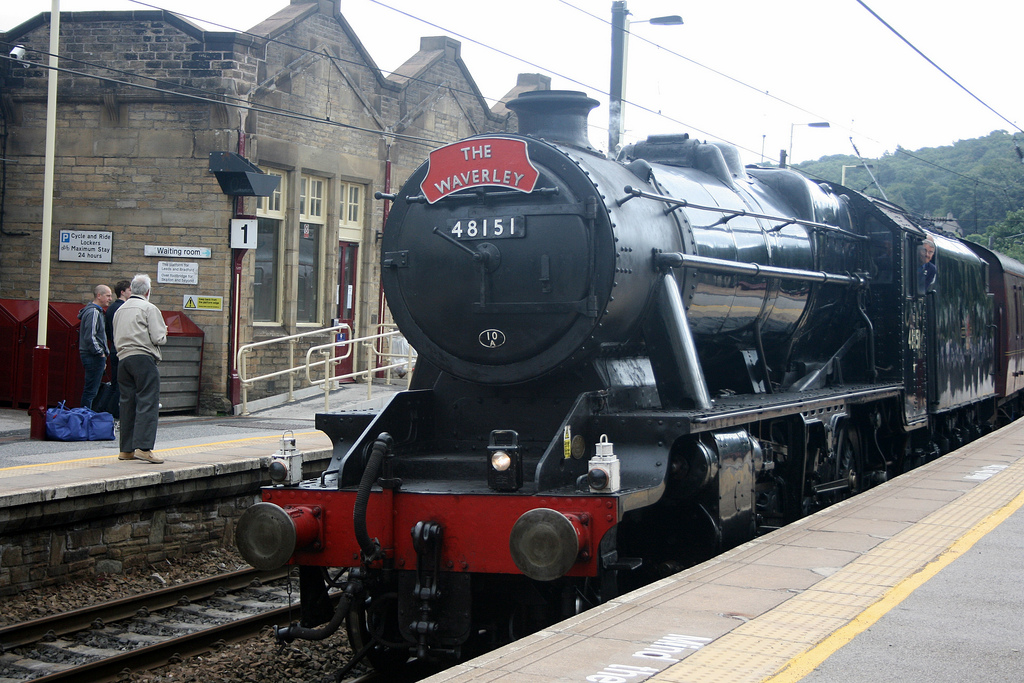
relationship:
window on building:
[240, 221, 280, 326] [3, 1, 550, 419]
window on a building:
[284, 219, 324, 325] [3, 1, 550, 419]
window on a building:
[340, 186, 363, 219] [3, 1, 550, 419]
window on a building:
[300, 177, 329, 213] [3, 1, 550, 419]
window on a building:
[261, 168, 284, 211] [3, 1, 550, 419]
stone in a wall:
[12, 534, 48, 563] [2, 461, 331, 592]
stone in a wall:
[60, 531, 95, 554] [2, 461, 331, 592]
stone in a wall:
[94, 518, 126, 535] [2, 461, 331, 592]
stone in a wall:
[125, 508, 149, 540] [2, 461, 331, 592]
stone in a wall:
[166, 506, 201, 519] [2, 461, 331, 592]